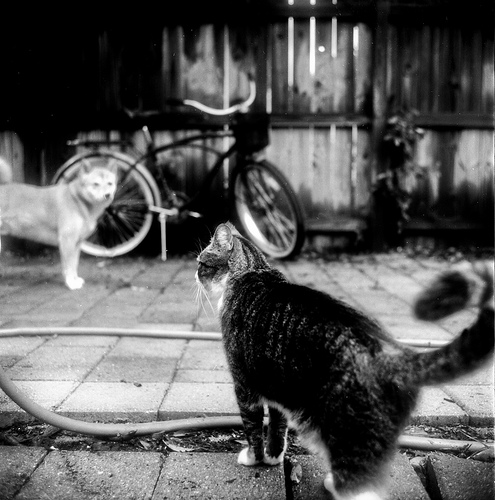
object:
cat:
[188, 215, 494, 499]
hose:
[0, 370, 494, 460]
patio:
[2, 232, 491, 498]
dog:
[1, 154, 121, 299]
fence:
[2, 2, 494, 250]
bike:
[47, 68, 314, 269]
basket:
[229, 98, 274, 156]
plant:
[353, 79, 426, 257]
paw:
[235, 445, 264, 468]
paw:
[263, 441, 287, 468]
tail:
[392, 277, 494, 387]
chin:
[197, 281, 211, 294]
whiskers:
[202, 290, 217, 318]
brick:
[55, 375, 170, 421]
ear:
[210, 222, 235, 253]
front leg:
[56, 218, 83, 293]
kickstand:
[157, 211, 169, 264]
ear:
[78, 156, 90, 176]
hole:
[1, 408, 494, 460]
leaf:
[160, 436, 197, 453]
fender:
[227, 150, 264, 205]